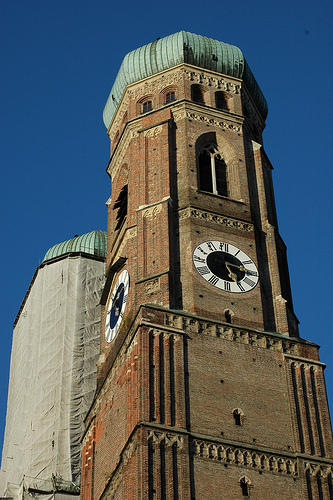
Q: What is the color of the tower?
A: Brown.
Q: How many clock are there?
A: 2.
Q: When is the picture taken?
A: Daytime.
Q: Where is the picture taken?
A: In the city.